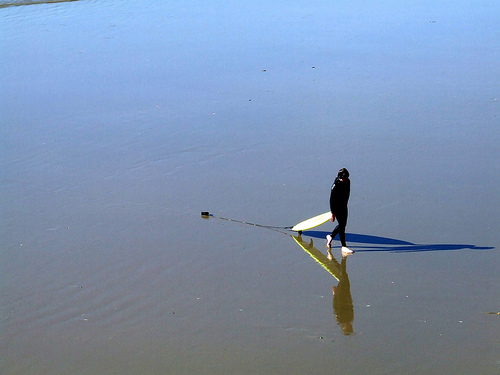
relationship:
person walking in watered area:
[328, 166, 356, 252] [3, 1, 498, 373]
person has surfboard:
[328, 166, 356, 252] [294, 209, 335, 234]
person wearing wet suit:
[328, 166, 356, 252] [328, 178, 352, 247]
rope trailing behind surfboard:
[210, 213, 292, 236] [294, 209, 335, 234]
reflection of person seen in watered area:
[341, 232, 493, 268] [3, 1, 498, 373]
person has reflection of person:
[328, 166, 356, 252] [341, 232, 493, 268]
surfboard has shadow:
[294, 209, 335, 234] [305, 226, 408, 250]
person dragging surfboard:
[328, 166, 356, 252] [294, 209, 335, 234]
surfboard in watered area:
[294, 209, 335, 234] [3, 1, 498, 373]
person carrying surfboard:
[328, 166, 356, 252] [294, 209, 335, 234]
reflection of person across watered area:
[341, 232, 493, 268] [3, 1, 498, 373]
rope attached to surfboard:
[210, 213, 292, 236] [294, 209, 335, 234]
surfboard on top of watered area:
[294, 209, 335, 234] [3, 1, 498, 373]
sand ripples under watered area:
[39, 254, 194, 341] [3, 1, 498, 373]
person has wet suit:
[328, 166, 356, 252] [328, 178, 352, 247]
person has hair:
[328, 166, 356, 252] [337, 167, 351, 183]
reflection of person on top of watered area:
[341, 232, 493, 268] [3, 1, 498, 373]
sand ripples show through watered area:
[39, 254, 194, 341] [3, 1, 498, 373]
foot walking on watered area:
[341, 247, 355, 253] [3, 1, 498, 373]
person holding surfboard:
[328, 166, 356, 252] [294, 209, 335, 234]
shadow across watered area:
[305, 226, 408, 250] [3, 1, 498, 373]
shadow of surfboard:
[305, 226, 408, 250] [294, 209, 335, 234]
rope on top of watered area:
[210, 213, 292, 236] [3, 1, 498, 373]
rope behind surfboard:
[210, 213, 292, 236] [294, 209, 335, 234]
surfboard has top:
[294, 209, 335, 234] [292, 213, 335, 229]